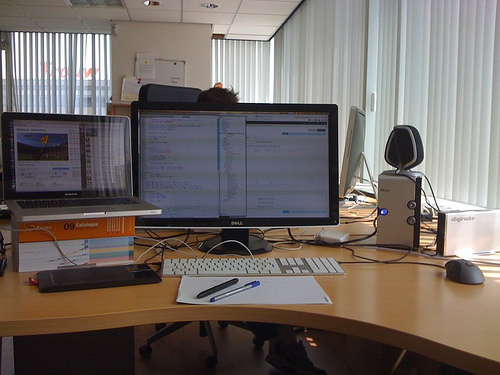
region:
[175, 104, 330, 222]
this is a monitor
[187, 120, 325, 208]
the monitor is on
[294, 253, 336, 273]
this is the keyboard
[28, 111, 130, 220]
this is the laptop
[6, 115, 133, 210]
it is beside the monitor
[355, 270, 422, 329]
this is the table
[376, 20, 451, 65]
these are the curtains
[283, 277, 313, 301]
this is a paper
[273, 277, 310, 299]
the paper is white incolor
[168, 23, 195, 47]
this is the wall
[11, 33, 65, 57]
blinds hanging on a door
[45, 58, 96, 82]
the logo of a store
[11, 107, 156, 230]
a small grey laptop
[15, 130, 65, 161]
a video on youtube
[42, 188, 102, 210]
the keyboard of a laptop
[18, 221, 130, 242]
the orange binding of a book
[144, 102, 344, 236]
a large monitor of a computer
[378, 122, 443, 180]
the speaker on a computer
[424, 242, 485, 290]
the mouse of a computer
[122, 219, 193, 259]
a bunch of wires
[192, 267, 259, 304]
two pens are on the paper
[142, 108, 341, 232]
the monitor is on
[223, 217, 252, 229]
dell is the logo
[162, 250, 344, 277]
the keyboard is white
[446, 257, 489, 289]
the mouse is grey and black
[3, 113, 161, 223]
the laptoop is on the books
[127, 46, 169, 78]
papers are on the wall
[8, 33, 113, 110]
the blinds are open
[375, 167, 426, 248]
the speaker is on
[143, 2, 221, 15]
two bulbs are on the ceiling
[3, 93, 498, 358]
A computer desk with accessories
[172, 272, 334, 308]
Two pens on a piece of paper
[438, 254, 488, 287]
A computer mouse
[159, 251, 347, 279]
A computer keyboard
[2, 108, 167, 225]
A laptop computer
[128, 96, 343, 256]
A computer monitor on a stand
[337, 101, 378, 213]
The side of a computer monitor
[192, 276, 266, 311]
Two ink pens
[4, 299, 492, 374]
The edge of a wooden desk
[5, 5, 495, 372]
An office work station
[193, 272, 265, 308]
a pair of pens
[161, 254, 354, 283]
a white computer keyboard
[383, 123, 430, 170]
a pair of computer speakers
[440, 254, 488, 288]
a silver computer mouse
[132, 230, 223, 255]
a tangle of electrical cords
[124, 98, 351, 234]
a dell computer screen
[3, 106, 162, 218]
a small silver laptop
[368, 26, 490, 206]
a few white vertical blinds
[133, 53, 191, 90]
a dry erase board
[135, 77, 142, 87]
a few colorful thumb tacks